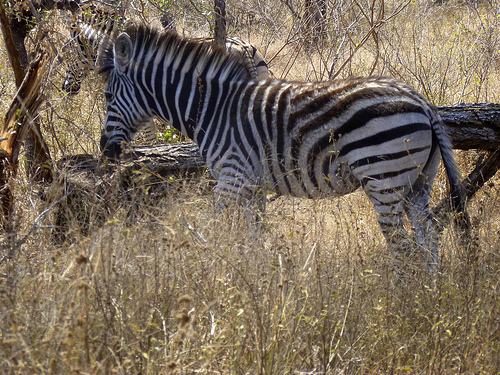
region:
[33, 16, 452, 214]
black and white animal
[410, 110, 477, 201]
tail of the zebra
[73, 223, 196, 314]
brown grass next to animal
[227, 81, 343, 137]
black stripes on animal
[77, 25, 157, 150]
head of the animal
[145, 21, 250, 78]
hair on the zebra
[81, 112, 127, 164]
nose of the animal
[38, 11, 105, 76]
zebra in the background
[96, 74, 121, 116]
eye of the zebra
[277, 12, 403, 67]
branches in the background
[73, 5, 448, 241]
zebra in the wild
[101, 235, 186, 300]
grass next to zebra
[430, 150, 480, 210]
tail of the zebra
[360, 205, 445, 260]
legs of the zebra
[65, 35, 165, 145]
head of the zebra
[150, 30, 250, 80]
hair on the back of zebra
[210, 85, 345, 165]
black and white animal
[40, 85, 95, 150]
branches on the tree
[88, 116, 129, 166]
nose of the zebra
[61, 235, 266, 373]
The grass is tall.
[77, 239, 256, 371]
The grass is brown.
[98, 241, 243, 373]
The grass is dry.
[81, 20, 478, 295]
The zebra is standing in the grass.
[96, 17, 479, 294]
The zebra is black and white.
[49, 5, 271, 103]
Another zebra is behind.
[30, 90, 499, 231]
A log is in the grass.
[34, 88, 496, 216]
The log is gray.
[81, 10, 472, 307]
The zebra is standing in the dry grass.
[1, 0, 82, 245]
The wood is brown.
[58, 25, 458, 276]
zebra standing in field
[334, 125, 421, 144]
stripes on zebra in field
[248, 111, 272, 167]
stripes on zebra in field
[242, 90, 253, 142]
stripes on zebra in field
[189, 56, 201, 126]
stripes on zebra in field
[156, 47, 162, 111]
stripes on zebra in field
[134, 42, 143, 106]
stripes on zebra in field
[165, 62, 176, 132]
stripes on zebra in field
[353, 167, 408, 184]
stripes on zebra in field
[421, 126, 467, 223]
tail of black and white zebra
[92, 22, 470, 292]
the zebra has stripes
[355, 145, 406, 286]
the leg of a zebra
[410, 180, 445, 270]
the leg of a zebra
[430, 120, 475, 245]
the tail of a zebra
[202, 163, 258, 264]
the leg of a zebra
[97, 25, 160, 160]
the head of a zebra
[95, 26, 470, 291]
this is a zebra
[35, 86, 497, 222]
this is a dead log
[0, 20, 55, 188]
this is a dry bark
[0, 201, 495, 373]
this is long grass